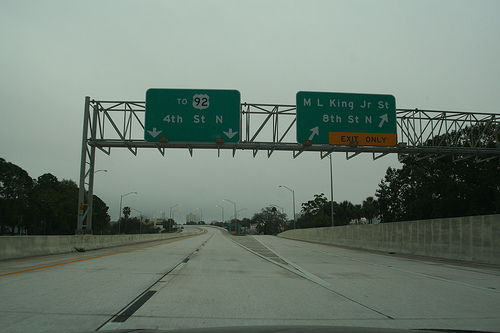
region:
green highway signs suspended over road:
[140, 77, 401, 165]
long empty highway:
[103, 195, 405, 330]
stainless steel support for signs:
[73, 90, 495, 161]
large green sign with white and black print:
[150, 85, 242, 147]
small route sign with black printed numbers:
[187, 90, 212, 112]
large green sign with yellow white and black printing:
[297, 87, 402, 153]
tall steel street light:
[277, 180, 297, 220]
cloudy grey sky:
[28, 13, 216, 81]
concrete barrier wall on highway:
[325, 220, 498, 270]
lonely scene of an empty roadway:
[10, 42, 487, 315]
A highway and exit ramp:
[128, 220, 328, 332]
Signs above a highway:
[133, 81, 415, 156]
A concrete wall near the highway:
[276, 221, 498, 266]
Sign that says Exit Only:
[326, 125, 394, 147]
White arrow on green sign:
[374, 109, 392, 131]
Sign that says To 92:
[171, 90, 213, 112]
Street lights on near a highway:
[208, 188, 243, 228]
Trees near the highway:
[217, 108, 497, 225]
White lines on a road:
[228, 235, 339, 300]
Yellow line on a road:
[1, 235, 156, 297]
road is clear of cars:
[5, 219, 400, 325]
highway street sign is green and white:
[295, 91, 402, 153]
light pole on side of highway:
[275, 182, 305, 226]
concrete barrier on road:
[6, 236, 83, 256]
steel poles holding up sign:
[80, 97, 100, 247]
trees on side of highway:
[402, 166, 489, 204]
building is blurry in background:
[181, 209, 207, 228]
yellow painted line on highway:
[5, 251, 155, 276]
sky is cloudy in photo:
[94, 18, 396, 65]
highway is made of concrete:
[220, 247, 255, 332]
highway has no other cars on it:
[37, 233, 447, 330]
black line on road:
[110, 289, 155, 321]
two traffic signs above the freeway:
[142, 85, 399, 153]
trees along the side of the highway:
[0, 154, 75, 239]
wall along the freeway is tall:
[347, 221, 498, 264]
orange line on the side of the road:
[12, 261, 59, 276]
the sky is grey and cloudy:
[195, 161, 275, 191]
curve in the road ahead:
[179, 224, 232, 251]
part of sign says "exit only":
[325, 127, 397, 149]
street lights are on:
[211, 195, 238, 227]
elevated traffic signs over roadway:
[5, 77, 490, 322]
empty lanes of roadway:
[0, 210, 485, 325]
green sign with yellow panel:
[295, 90, 395, 150]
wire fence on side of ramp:
[275, 206, 495, 266]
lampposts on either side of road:
[92, 147, 337, 238]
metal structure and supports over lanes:
[75, 90, 495, 232]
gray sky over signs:
[10, 10, 490, 115]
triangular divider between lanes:
[215, 221, 335, 291]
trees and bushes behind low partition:
[0, 157, 180, 257]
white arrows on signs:
[141, 108, 391, 143]